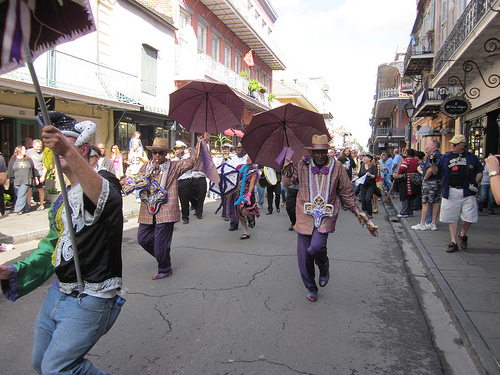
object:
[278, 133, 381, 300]
men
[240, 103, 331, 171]
umbrella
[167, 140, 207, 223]
men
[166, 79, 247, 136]
umbrella